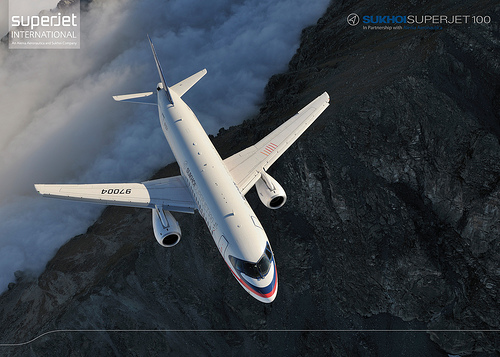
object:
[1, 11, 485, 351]
terrain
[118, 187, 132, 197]
number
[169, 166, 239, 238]
shadow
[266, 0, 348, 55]
sky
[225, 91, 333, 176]
wing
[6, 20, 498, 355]
sky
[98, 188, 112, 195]
numbers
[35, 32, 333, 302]
airplane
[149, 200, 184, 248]
engine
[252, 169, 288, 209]
engine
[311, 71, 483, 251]
mountain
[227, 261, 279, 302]
front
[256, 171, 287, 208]
jet's engine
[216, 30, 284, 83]
clouds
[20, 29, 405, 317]
sky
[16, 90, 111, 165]
clouds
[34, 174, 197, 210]
wing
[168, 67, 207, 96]
wing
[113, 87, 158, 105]
wing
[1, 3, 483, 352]
mountains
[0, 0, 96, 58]
cloud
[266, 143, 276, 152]
stripe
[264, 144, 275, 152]
stripe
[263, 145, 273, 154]
stripe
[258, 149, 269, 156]
stripe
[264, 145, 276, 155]
stripe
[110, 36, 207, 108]
tail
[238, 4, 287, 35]
clouds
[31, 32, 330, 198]
top